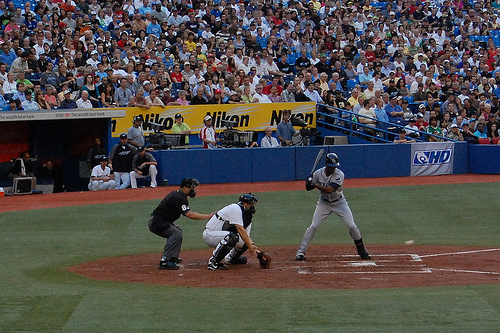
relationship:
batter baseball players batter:
[295, 152, 372, 261] [295, 152, 372, 261]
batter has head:
[295, 152, 372, 261] [324, 149, 339, 175]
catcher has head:
[203, 192, 261, 272] [236, 193, 259, 215]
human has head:
[147, 178, 217, 270] [173, 176, 200, 197]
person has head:
[109, 132, 143, 188] [116, 132, 130, 144]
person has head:
[85, 154, 116, 191] [97, 154, 110, 170]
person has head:
[73, 88, 94, 106] [79, 88, 90, 100]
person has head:
[40, 81, 60, 92] [40, 86, 52, 95]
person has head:
[5, 50, 35, 80] [17, 50, 32, 63]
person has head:
[0, 70, 20, 97] [6, 70, 19, 82]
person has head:
[233, 44, 249, 71] [235, 46, 244, 57]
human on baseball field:
[147, 178, 217, 270] [0, 161, 499, 328]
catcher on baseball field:
[203, 192, 261, 272] [0, 161, 499, 328]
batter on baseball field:
[295, 152, 372, 261] [0, 161, 499, 328]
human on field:
[147, 178, 217, 270] [30, 169, 486, 329]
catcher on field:
[203, 192, 261, 272] [30, 169, 486, 329]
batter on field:
[295, 152, 372, 261] [30, 169, 486, 329]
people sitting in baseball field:
[1, 0, 498, 141] [0, 0, 499, 328]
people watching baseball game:
[1, 0, 498, 141] [120, 145, 388, 276]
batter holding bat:
[295, 152, 372, 261] [303, 145, 330, 189]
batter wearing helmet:
[295, 152, 372, 261] [320, 151, 342, 167]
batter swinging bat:
[295, 152, 372, 261] [303, 146, 324, 181]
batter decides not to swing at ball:
[295, 152, 372, 261] [403, 235, 413, 248]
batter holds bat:
[295, 152, 372, 261] [304, 145, 324, 185]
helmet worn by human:
[323, 148, 348, 168] [303, 145, 366, 275]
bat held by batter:
[308, 141, 321, 179] [295, 152, 372, 261]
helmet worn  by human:
[323, 148, 348, 168] [294, 142, 370, 264]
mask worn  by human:
[242, 193, 256, 210] [145, 178, 196, 269]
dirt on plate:
[351, 254, 369, 270] [346, 255, 378, 271]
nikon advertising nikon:
[136, 110, 311, 130] [136, 110, 311, 130]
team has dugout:
[15, 126, 163, 190] [2, 119, 113, 188]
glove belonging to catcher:
[259, 247, 272, 271] [200, 189, 274, 271]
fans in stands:
[0, 1, 497, 143] [9, 3, 484, 143]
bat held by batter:
[308, 141, 321, 179] [291, 143, 371, 266]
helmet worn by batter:
[323, 148, 348, 168] [301, 146, 375, 265]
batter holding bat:
[295, 152, 372, 261] [312, 147, 322, 180]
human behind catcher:
[147, 178, 217, 270] [202, 194, 270, 271]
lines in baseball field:
[299, 262, 436, 277] [0, 0, 499, 328]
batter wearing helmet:
[295, 152, 372, 261] [324, 152, 337, 166]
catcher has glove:
[203, 189, 274, 278] [256, 251, 272, 269]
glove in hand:
[256, 251, 272, 269] [251, 240, 270, 269]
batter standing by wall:
[295, 152, 372, 261] [145, 150, 408, 186]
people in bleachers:
[136, 148, 372, 269] [5, 3, 484, 137]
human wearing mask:
[147, 178, 217, 270] [184, 185, 200, 201]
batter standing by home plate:
[295, 152, 372, 261] [349, 259, 378, 267]